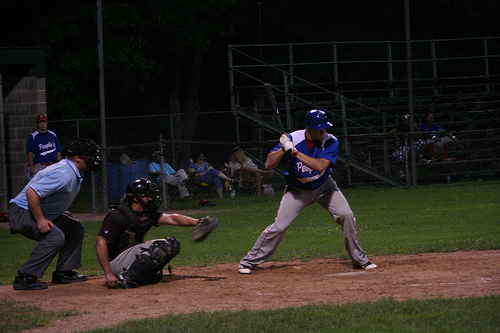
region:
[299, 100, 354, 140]
shiny blue helmet on head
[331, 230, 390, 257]
wrinkles in gray pants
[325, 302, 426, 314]
green grass on field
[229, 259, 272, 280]
black and white sneakers on foot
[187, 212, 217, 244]
man holding black glove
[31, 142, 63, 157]
white stripe on blue jersey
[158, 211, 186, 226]
bulges in man's arm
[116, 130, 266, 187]
people sitting in chairs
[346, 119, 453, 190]
large fence at side of field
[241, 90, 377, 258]
man holding bat in his hand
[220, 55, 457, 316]
Batter is ready to hit the ball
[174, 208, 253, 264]
Catcher holds out his mitt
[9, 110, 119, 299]
Umpire standing behind the catcher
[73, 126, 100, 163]
Umpire wearing a face mask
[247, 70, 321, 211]
Batter is holding the bat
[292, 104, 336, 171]
Batter wearing a helmet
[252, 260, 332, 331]
The field has dirt on it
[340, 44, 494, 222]
Stands are made of metal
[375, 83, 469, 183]
Fans sitting on the stands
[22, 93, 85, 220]
Coach standing by the dugout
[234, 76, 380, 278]
Baseball player holding a bat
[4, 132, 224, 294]
Umpire is behind the catcher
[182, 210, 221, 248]
A black leather glove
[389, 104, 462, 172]
People sitting on bleachers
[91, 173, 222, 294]
A catcher is crouched down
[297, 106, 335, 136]
The helmet is blue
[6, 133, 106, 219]
Umpire is wearing a blue shirt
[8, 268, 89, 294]
A pair of black shoes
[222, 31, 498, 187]
Bleachers in the background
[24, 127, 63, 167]
A shirt is blue and white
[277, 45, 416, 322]
A man playing baseball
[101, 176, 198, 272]
A man playing baseball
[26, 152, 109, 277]
A man playing baseball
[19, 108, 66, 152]
A man playing baseball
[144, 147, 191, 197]
A man watching from a distance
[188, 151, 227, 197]
A man watching from a distance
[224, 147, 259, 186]
A man watching from a distance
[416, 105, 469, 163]
A man watching from a distance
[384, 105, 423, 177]
A man watching from a distance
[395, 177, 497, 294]
A green and bear field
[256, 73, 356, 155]
a man holding a bat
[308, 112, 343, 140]
a man wearing a helmet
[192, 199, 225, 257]
a man wearing a catchers mitt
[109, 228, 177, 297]
a man wearing safety gear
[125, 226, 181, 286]
a man wearing knee pads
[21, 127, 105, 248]
a man bent over with his hand on his thighs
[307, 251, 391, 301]
home plate on a baseball field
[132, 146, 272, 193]
three people sitting behind a fence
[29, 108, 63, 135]
a man wearing a red hat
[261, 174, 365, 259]
a man wearing grey pants